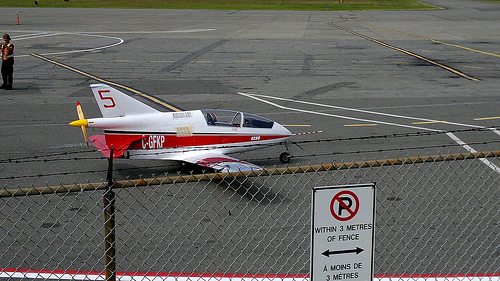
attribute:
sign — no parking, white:
[308, 178, 376, 280]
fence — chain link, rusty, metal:
[0, 123, 499, 280]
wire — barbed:
[1, 120, 500, 191]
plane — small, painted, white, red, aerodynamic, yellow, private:
[71, 80, 296, 182]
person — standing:
[0, 31, 17, 94]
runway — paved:
[1, 5, 500, 279]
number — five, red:
[97, 88, 119, 113]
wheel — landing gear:
[278, 150, 297, 166]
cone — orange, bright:
[15, 11, 24, 28]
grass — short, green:
[0, 0, 447, 10]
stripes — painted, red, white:
[1, 266, 500, 280]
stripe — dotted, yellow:
[160, 116, 499, 132]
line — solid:
[30, 51, 192, 116]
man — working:
[0, 29, 20, 92]